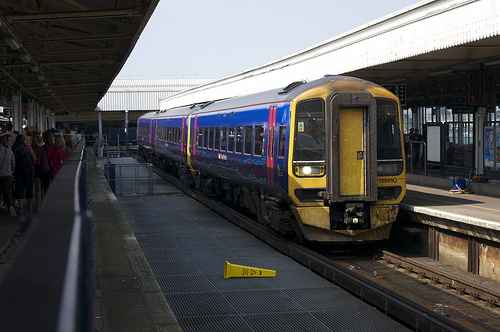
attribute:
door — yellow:
[333, 101, 370, 197]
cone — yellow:
[219, 256, 283, 282]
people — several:
[0, 117, 78, 219]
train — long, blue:
[123, 69, 417, 250]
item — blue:
[449, 172, 471, 196]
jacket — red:
[39, 142, 73, 172]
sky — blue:
[159, 2, 336, 43]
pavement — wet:
[87, 144, 192, 327]